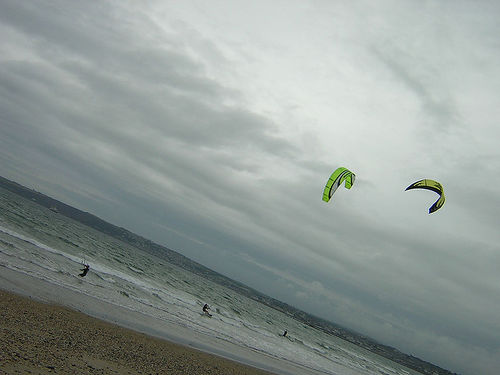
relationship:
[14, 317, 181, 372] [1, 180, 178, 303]
sand near water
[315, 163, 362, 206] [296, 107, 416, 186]
green kite in sky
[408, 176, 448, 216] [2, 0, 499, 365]
kite in sky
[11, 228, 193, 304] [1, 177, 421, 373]
wave in the water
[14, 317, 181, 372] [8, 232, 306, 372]
sand on beach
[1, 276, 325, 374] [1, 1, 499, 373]
beach under gray sky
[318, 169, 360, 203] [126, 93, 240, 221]
kite in sky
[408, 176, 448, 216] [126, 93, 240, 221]
kite in sky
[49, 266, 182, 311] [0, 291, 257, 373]
water washes onto shore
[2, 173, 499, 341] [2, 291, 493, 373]
ocean and a sandy beach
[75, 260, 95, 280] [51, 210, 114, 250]
person/water in water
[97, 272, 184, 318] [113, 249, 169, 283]
wave in water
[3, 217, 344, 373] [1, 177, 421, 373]
wave in water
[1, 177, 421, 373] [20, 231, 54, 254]
water in wave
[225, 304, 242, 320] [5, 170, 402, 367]
wave in water